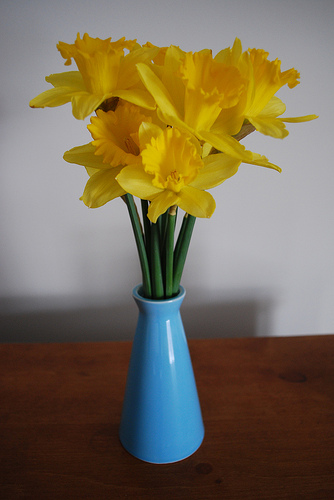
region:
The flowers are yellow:
[75, 36, 279, 187]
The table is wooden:
[220, 407, 328, 483]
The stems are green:
[116, 181, 206, 279]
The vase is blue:
[135, 309, 200, 494]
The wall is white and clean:
[252, 200, 314, 268]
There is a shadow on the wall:
[178, 254, 291, 381]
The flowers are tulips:
[67, 30, 264, 175]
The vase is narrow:
[98, 257, 205, 482]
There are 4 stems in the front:
[116, 184, 208, 301]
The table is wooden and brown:
[36, 393, 97, 468]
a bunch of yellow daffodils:
[20, 22, 321, 270]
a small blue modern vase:
[103, 272, 206, 470]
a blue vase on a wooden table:
[13, 278, 330, 471]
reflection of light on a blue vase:
[157, 308, 181, 372]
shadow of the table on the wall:
[0, 284, 285, 354]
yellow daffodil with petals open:
[126, 118, 235, 223]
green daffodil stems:
[122, 210, 199, 296]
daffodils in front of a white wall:
[26, 16, 324, 312]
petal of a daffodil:
[62, 139, 111, 170]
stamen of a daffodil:
[106, 125, 138, 157]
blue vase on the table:
[112, 269, 210, 480]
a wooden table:
[11, 363, 92, 480]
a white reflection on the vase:
[156, 311, 178, 378]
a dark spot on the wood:
[188, 455, 222, 486]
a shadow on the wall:
[2, 273, 280, 351]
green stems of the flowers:
[114, 187, 198, 293]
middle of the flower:
[145, 150, 199, 220]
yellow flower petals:
[84, 121, 233, 217]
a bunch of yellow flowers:
[31, 13, 308, 246]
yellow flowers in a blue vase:
[21, 28, 327, 467]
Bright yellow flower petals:
[39, 20, 142, 108]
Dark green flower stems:
[135, 225, 181, 283]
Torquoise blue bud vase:
[130, 284, 210, 457]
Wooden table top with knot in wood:
[230, 366, 316, 467]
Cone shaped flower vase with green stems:
[107, 274, 222, 472]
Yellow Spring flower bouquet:
[31, 17, 323, 226]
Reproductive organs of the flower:
[167, 165, 184, 189]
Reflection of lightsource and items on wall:
[142, 308, 178, 378]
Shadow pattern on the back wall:
[73, 274, 269, 334]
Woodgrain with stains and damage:
[38, 382, 108, 489]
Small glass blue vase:
[117, 290, 210, 463]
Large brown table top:
[9, 349, 106, 397]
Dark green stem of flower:
[134, 222, 157, 296]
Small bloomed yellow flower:
[117, 135, 234, 211]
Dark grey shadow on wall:
[198, 292, 276, 330]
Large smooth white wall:
[285, 231, 319, 291]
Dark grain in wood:
[271, 366, 311, 391]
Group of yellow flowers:
[80, 48, 237, 204]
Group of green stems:
[129, 217, 195, 297]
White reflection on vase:
[163, 316, 180, 375]